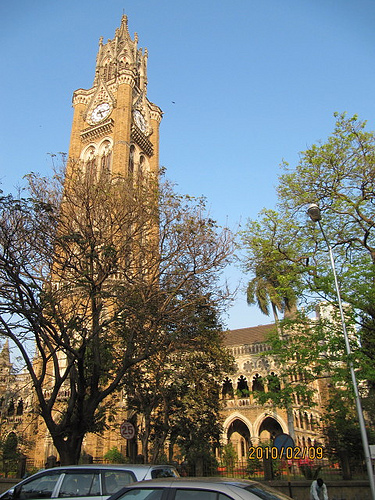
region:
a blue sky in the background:
[188, 12, 353, 110]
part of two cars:
[11, 459, 269, 498]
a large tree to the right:
[296, 116, 367, 478]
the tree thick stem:
[56, 435, 76, 462]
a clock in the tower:
[86, 102, 111, 124]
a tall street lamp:
[303, 203, 373, 495]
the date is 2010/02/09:
[247, 447, 324, 460]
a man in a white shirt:
[310, 477, 325, 498]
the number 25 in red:
[121, 424, 131, 436]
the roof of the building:
[230, 326, 265, 343]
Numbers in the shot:
[232, 432, 337, 469]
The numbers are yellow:
[242, 434, 343, 469]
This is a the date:
[230, 436, 349, 472]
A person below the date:
[292, 474, 331, 498]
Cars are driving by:
[0, 440, 306, 498]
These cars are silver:
[4, 448, 290, 498]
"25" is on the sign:
[107, 419, 150, 442]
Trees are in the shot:
[2, 166, 272, 473]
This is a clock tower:
[59, 2, 170, 252]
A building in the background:
[7, 276, 356, 477]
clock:
[85, 85, 106, 132]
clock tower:
[79, 29, 165, 161]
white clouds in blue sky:
[208, 57, 248, 118]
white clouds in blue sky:
[201, 146, 239, 191]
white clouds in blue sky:
[250, 45, 289, 94]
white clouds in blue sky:
[183, 44, 224, 79]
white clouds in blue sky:
[18, 14, 50, 52]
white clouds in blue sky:
[174, 36, 251, 96]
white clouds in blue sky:
[213, 80, 269, 145]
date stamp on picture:
[237, 438, 346, 474]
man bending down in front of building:
[311, 473, 336, 499]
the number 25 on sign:
[108, 414, 144, 454]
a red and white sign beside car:
[119, 418, 155, 462]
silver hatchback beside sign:
[8, 461, 179, 497]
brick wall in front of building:
[276, 481, 372, 499]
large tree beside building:
[1, 186, 216, 451]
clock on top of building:
[82, 93, 130, 124]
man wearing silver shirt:
[305, 481, 331, 499]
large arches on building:
[218, 404, 258, 444]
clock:
[78, 93, 118, 123]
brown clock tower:
[84, 7, 167, 180]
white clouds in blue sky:
[211, 32, 248, 87]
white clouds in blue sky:
[201, 123, 243, 177]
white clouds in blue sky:
[269, 32, 334, 93]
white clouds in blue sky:
[27, 23, 68, 62]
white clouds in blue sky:
[2, 54, 50, 113]